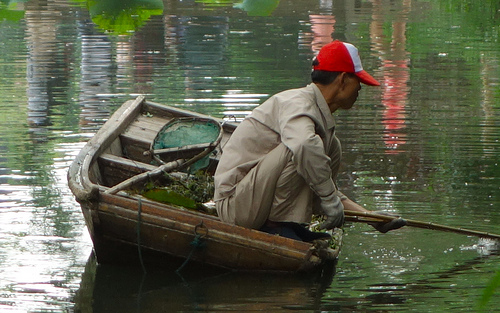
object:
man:
[210, 38, 407, 245]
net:
[479, 235, 500, 252]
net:
[151, 117, 224, 177]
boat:
[65, 94, 346, 282]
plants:
[140, 177, 217, 210]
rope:
[135, 198, 201, 274]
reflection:
[368, 0, 414, 156]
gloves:
[364, 210, 407, 234]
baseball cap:
[310, 39, 383, 86]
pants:
[214, 132, 316, 231]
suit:
[211, 82, 350, 231]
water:
[0, 0, 499, 313]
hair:
[311, 56, 357, 85]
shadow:
[339, 0, 500, 222]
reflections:
[358, 0, 500, 90]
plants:
[0, 0, 165, 40]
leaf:
[141, 186, 202, 210]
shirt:
[209, 82, 342, 210]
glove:
[318, 188, 346, 231]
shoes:
[283, 220, 332, 243]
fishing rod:
[343, 209, 499, 242]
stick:
[142, 142, 215, 157]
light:
[0, 121, 101, 313]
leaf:
[83, 0, 165, 36]